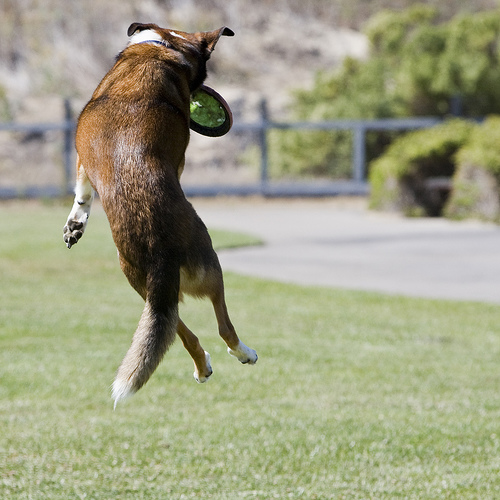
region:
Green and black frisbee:
[190, 81, 233, 139]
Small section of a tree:
[291, 52, 433, 192]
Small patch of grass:
[351, 401, 483, 498]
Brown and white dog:
[64, 22, 179, 336]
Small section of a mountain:
[260, 15, 337, 76]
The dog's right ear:
[208, 21, 242, 54]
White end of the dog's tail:
[116, 300, 186, 397]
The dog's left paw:
[55, 215, 90, 256]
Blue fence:
[265, 111, 365, 196]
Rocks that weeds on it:
[384, 127, 499, 215]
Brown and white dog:
[61, 19, 259, 413]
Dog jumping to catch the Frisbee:
[60, 18, 273, 498]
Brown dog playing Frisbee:
[6, 7, 491, 494]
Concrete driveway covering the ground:
[192, 197, 497, 302]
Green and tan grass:
[2, 407, 499, 499]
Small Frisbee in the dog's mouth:
[187, 82, 232, 138]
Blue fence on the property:
[2, 93, 499, 201]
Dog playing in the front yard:
[15, 9, 481, 483]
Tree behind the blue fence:
[277, 21, 499, 193]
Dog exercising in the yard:
[60, 19, 321, 446]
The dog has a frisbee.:
[41, 11, 286, 427]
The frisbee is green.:
[171, 68, 246, 144]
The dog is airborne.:
[40, 11, 287, 411]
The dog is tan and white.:
[58, 12, 277, 411]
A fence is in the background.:
[0, 87, 485, 196]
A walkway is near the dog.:
[180, 184, 498, 309]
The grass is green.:
[2, 301, 498, 498]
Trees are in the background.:
[252, 4, 497, 195]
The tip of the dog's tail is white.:
[92, 365, 156, 416]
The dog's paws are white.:
[55, 177, 101, 257]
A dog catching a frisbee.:
[35, 5, 310, 442]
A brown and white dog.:
[32, 10, 289, 424]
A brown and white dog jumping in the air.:
[47, 8, 324, 420]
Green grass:
[285, 313, 480, 487]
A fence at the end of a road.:
[256, 90, 458, 203]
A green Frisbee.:
[187, 75, 242, 147]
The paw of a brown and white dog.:
[35, 167, 109, 262]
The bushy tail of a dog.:
[105, 248, 194, 404]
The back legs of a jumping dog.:
[117, 257, 281, 418]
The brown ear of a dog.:
[188, 9, 240, 64]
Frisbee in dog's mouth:
[172, 73, 232, 140]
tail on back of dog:
[106, 263, 188, 413]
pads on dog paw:
[58, 216, 87, 258]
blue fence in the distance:
[268, 109, 380, 207]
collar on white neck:
[123, 26, 170, 58]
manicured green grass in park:
[286, 359, 401, 463]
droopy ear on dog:
[206, 20, 240, 52]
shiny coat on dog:
[91, 125, 160, 191]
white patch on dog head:
[164, 28, 193, 43]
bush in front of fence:
[373, 117, 482, 211]